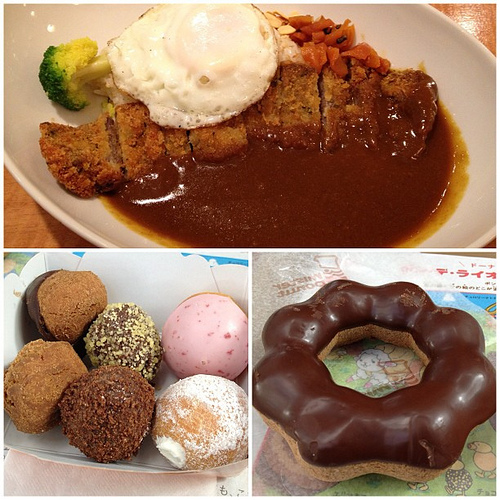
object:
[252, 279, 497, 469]
frosting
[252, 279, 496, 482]
crueller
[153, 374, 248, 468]
topping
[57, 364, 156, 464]
coconut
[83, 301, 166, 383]
almond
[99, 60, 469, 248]
gravy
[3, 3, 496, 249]
plate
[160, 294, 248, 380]
icing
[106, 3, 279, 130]
potatoes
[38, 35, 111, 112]
broccoli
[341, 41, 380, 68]
carrots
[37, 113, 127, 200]
piece of meat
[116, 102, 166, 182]
piece of meat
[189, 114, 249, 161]
piece of meat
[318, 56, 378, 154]
piece of meat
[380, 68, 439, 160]
piece of meat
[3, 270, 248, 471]
donut holes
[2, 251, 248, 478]
paper bowl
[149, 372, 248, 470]
doughnut hole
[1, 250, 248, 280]
edge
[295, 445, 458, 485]
edge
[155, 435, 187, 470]
cream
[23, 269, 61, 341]
icing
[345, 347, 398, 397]
bunny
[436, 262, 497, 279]
writing